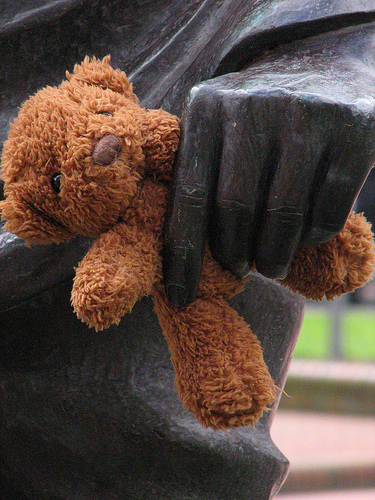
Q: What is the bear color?
A: Brown.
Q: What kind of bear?
A: Teddy.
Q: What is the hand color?
A: Black.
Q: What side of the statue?
A: Left.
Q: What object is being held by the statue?
A: A bear.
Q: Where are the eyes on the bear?
A: On it's head.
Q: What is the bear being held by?
A: A statue.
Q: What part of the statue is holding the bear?
A: The statue's hand.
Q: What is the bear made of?
A: Fur.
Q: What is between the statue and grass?
A: A fence.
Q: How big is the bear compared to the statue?
A: The teddy bear is small.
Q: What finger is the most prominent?
A: Index finger.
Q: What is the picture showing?
A: A bear and a statue.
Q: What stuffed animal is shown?
A: Teddy bear.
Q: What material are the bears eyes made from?
A: Marble.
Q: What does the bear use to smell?
A: Nose.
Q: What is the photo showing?
A: A bear and a statue.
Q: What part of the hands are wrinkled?
A: Knuckles.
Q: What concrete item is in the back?
A: Concrete steps.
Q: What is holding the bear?
A: A hand.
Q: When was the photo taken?
A: Day time.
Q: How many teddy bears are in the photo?
A: 1.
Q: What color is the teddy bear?
A: Brown.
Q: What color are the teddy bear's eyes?
A: Black.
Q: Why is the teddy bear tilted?
A: The statue.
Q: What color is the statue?
A: Black.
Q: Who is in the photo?
A: No one.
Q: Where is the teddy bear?
A: On the statue's hand.